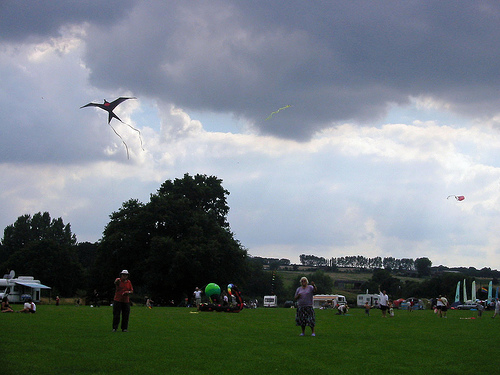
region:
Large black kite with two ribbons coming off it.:
[79, 97, 144, 160]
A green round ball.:
[205, 282, 221, 299]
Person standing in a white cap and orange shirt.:
[110, 269, 132, 332]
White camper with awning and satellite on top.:
[0, 271, 50, 308]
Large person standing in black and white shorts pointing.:
[293, 277, 316, 338]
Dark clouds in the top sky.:
[0, 2, 498, 138]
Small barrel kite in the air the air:
[441, 190, 474, 219]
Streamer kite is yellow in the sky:
[243, 91, 303, 122]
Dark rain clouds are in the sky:
[16, 9, 469, 208]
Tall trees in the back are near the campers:
[11, 135, 288, 335]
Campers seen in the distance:
[309, 280, 394, 314]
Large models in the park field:
[436, 274, 498, 334]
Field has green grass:
[17, 300, 484, 370]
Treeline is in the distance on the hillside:
[295, 250, 440, 270]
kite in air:
[77, 78, 142, 138]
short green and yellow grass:
[405, 333, 453, 357]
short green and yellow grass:
[145, 318, 182, 343]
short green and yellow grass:
[41, 329, 95, 344]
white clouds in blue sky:
[184, 18, 242, 75]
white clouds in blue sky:
[387, 211, 441, 252]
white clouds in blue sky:
[332, 29, 419, 89]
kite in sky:
[81, 84, 134, 125]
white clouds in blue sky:
[351, 59, 386, 78]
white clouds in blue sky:
[432, 119, 454, 146]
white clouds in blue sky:
[255, 61, 312, 125]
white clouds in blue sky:
[60, 29, 117, 61]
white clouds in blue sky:
[22, 123, 77, 179]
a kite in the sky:
[82, 66, 169, 165]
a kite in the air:
[77, 66, 150, 156]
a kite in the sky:
[437, 180, 472, 227]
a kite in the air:
[449, 176, 470, 220]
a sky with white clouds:
[22, 26, 474, 247]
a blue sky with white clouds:
[17, 18, 431, 243]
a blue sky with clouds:
[15, 15, 465, 300]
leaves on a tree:
[112, 170, 279, 290]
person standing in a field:
[290, 284, 340, 368]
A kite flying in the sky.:
[79, 94, 146, 159]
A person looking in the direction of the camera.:
[292, 275, 317, 334]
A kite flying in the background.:
[446, 191, 466, 202]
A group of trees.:
[0, 172, 282, 302]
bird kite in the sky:
[77, 93, 149, 163]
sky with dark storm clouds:
[1, 2, 498, 167]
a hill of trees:
[252, 248, 497, 305]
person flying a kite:
[75, 91, 153, 333]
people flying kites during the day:
[3, 87, 498, 340]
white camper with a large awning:
[2, 270, 51, 317]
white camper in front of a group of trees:
[2, 208, 82, 303]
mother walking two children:
[361, 288, 397, 321]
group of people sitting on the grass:
[0, 293, 38, 317]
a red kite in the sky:
[440, 190, 470, 207]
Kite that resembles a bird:
[80, 93, 141, 158]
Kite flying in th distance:
[445, 191, 466, 205]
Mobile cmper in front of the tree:
[0, 273, 50, 307]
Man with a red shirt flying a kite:
[106, 261, 138, 336]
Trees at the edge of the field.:
[0, 175, 287, 313]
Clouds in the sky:
[0, 6, 498, 258]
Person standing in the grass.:
[288, 271, 318, 340]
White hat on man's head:
[119, 266, 131, 276]